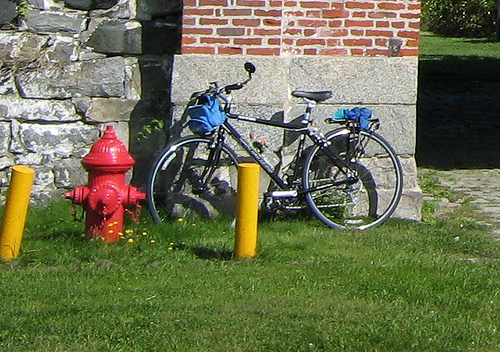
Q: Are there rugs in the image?
A: No, there are no rugs.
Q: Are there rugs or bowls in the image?
A: No, there are no rugs or bowls.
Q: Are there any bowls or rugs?
A: No, there are no rugs or bowls.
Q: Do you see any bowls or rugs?
A: No, there are no rugs or bowls.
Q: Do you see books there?
A: No, there are no books.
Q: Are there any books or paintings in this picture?
A: No, there are no books or paintings.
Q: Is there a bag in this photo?
A: Yes, there is a bag.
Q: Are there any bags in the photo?
A: Yes, there is a bag.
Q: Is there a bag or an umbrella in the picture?
A: Yes, there is a bag.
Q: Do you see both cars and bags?
A: No, there is a bag but no cars.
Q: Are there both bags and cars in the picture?
A: No, there is a bag but no cars.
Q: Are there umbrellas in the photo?
A: No, there are no umbrellas.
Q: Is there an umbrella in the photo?
A: No, there are no umbrellas.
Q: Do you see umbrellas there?
A: No, there are no umbrellas.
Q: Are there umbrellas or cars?
A: No, there are no umbrellas or cars.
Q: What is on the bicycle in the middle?
A: The bag is on the bicycle.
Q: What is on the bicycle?
A: The bag is on the bicycle.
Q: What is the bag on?
A: The bag is on the bicycle.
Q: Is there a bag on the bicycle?
A: Yes, there is a bag on the bicycle.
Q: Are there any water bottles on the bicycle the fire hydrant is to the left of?
A: No, there is a bag on the bicycle.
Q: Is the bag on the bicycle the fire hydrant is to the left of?
A: Yes, the bag is on the bicycle.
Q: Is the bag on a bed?
A: No, the bag is on the bicycle.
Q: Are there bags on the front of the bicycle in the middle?
A: Yes, there is a bag on the front of the bicycle.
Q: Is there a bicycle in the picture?
A: Yes, there is a bicycle.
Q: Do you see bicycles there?
A: Yes, there is a bicycle.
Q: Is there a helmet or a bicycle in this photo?
A: Yes, there is a bicycle.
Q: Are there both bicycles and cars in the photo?
A: No, there is a bicycle but no cars.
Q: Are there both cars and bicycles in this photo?
A: No, there is a bicycle but no cars.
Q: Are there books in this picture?
A: No, there are no books.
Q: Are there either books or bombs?
A: No, there are no books or bombs.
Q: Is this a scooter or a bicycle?
A: This is a bicycle.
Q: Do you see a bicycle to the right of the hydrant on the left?
A: Yes, there is a bicycle to the right of the fire hydrant.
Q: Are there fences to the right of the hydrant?
A: No, there is a bicycle to the right of the hydrant.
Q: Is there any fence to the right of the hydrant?
A: No, there is a bicycle to the right of the hydrant.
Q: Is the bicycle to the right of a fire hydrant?
A: Yes, the bicycle is to the right of a fire hydrant.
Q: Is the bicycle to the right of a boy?
A: No, the bicycle is to the right of a fire hydrant.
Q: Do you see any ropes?
A: No, there are no ropes.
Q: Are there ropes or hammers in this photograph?
A: No, there are no ropes or hammers.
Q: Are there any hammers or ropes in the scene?
A: No, there are no ropes or hammers.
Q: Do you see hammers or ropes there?
A: No, there are no ropes or hammers.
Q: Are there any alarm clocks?
A: No, there are no alarm clocks.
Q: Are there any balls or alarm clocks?
A: No, there are no alarm clocks or balls.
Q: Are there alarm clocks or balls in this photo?
A: No, there are no alarm clocks or balls.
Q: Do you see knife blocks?
A: No, there are no knife blocks.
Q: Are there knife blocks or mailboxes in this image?
A: No, there are no knife blocks or mailboxes.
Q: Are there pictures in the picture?
A: No, there are no pictures.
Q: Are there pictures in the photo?
A: No, there are no pictures.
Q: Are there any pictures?
A: No, there are no pictures.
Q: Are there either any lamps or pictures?
A: No, there are no pictures or lamps.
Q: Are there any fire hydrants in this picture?
A: Yes, there is a fire hydrant.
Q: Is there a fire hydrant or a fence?
A: Yes, there is a fire hydrant.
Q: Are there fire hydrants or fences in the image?
A: Yes, there is a fire hydrant.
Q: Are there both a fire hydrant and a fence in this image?
A: No, there is a fire hydrant but no fences.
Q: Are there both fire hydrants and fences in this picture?
A: No, there is a fire hydrant but no fences.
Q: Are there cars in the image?
A: No, there are no cars.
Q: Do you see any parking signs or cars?
A: No, there are no cars or parking signs.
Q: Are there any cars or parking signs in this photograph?
A: No, there are no cars or parking signs.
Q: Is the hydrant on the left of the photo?
A: Yes, the hydrant is on the left of the image.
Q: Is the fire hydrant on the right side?
A: No, the fire hydrant is on the left of the image.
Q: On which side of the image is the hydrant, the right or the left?
A: The hydrant is on the left of the image.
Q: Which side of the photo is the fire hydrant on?
A: The fire hydrant is on the left of the image.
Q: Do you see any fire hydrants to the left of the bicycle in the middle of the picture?
A: Yes, there is a fire hydrant to the left of the bicycle.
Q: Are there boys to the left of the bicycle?
A: No, there is a fire hydrant to the left of the bicycle.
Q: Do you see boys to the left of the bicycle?
A: No, there is a fire hydrant to the left of the bicycle.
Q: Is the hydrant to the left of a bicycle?
A: Yes, the hydrant is to the left of a bicycle.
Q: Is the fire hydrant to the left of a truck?
A: No, the fire hydrant is to the left of a bicycle.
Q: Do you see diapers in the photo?
A: No, there are no diapers.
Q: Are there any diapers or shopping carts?
A: No, there are no diapers or shopping carts.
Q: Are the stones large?
A: Yes, the stones are large.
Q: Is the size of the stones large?
A: Yes, the stones are large.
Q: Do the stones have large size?
A: Yes, the stones are large.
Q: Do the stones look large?
A: Yes, the stones are large.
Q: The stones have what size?
A: The stones are large.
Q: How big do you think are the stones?
A: The stones are large.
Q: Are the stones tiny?
A: No, the stones are large.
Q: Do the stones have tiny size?
A: No, the stones are large.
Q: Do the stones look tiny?
A: No, the stones are large.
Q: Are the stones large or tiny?
A: The stones are large.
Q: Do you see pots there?
A: No, there are no pots.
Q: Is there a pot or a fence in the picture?
A: No, there are no pots or fences.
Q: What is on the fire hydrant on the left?
A: The chain is on the fire hydrant.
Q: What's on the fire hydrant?
A: The chain is on the fire hydrant.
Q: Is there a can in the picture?
A: No, there are no cans.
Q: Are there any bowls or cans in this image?
A: No, there are no cans or bowls.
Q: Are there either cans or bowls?
A: No, there are no cans or bowls.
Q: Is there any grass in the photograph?
A: Yes, there is grass.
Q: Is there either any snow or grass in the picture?
A: Yes, there is grass.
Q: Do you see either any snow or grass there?
A: Yes, there is grass.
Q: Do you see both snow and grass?
A: No, there is grass but no snow.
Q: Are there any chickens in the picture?
A: No, there are no chickens.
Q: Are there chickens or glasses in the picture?
A: No, there are no chickens or glasses.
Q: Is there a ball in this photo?
A: No, there are no balls.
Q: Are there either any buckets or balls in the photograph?
A: No, there are no balls or buckets.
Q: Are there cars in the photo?
A: No, there are no cars.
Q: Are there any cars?
A: No, there are no cars.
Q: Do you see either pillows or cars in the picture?
A: No, there are no cars or pillows.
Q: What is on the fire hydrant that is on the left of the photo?
A: The chain is on the hydrant.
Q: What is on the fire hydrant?
A: The chain is on the hydrant.